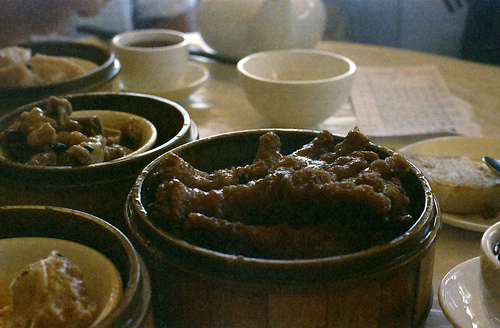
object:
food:
[142, 126, 415, 260]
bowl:
[123, 128, 442, 328]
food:
[0, 95, 142, 166]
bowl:
[1, 91, 200, 224]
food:
[0, 249, 96, 328]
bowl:
[0, 202, 154, 328]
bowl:
[237, 48, 356, 128]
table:
[1, 39, 500, 327]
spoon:
[482, 157, 500, 178]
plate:
[396, 135, 499, 232]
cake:
[412, 155, 500, 215]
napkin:
[349, 66, 482, 138]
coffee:
[111, 29, 210, 95]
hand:
[0, 0, 102, 44]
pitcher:
[193, 0, 328, 59]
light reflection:
[271, 71, 279, 81]